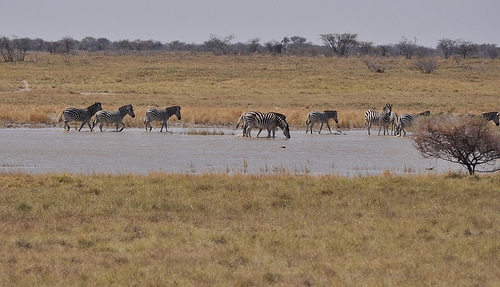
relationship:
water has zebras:
[103, 137, 259, 169] [53, 93, 499, 141]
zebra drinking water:
[238, 111, 292, 141] [103, 137, 259, 169]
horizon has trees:
[170, 42, 291, 65] [320, 28, 485, 78]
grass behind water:
[158, 66, 223, 80] [103, 137, 259, 169]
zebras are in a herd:
[53, 93, 499, 141] [146, 92, 410, 141]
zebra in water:
[238, 111, 292, 141] [103, 137, 259, 169]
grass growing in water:
[158, 66, 223, 80] [103, 137, 259, 169]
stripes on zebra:
[255, 118, 272, 126] [238, 111, 292, 141]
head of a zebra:
[170, 106, 185, 120] [238, 111, 292, 141]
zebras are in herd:
[53, 93, 499, 141] [146, 92, 410, 141]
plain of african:
[0, 55, 499, 102] [196, 58, 483, 102]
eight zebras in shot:
[68, 72, 498, 123] [9, 12, 497, 240]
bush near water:
[410, 108, 499, 176] [103, 137, 259, 169]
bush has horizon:
[410, 108, 499, 176] [0, 32, 500, 57]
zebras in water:
[53, 93, 499, 141] [103, 137, 259, 169]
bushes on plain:
[324, 42, 440, 74] [222, 40, 308, 71]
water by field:
[103, 137, 259, 169] [27, 60, 443, 96]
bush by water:
[410, 108, 499, 176] [103, 137, 259, 169]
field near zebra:
[27, 60, 443, 96] [238, 111, 292, 141]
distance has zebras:
[47, 37, 138, 56] [53, 93, 499, 141]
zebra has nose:
[238, 111, 292, 141] [177, 115, 184, 119]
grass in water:
[158, 66, 223, 80] [103, 137, 259, 169]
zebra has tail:
[238, 111, 292, 141] [233, 115, 243, 130]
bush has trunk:
[410, 108, 499, 176] [457, 163, 482, 177]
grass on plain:
[158, 66, 223, 80] [222, 40, 308, 71]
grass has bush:
[158, 66, 223, 80] [410, 108, 499, 176]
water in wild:
[103, 137, 259, 169] [9, 12, 497, 240]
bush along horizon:
[410, 108, 499, 176] [170, 42, 291, 65]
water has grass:
[103, 137, 259, 169] [158, 66, 223, 80]